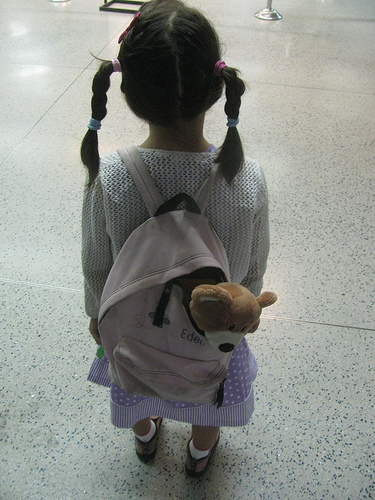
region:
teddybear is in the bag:
[181, 278, 290, 359]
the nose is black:
[219, 341, 237, 359]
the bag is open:
[109, 248, 235, 411]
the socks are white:
[183, 439, 209, 456]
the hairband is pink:
[109, 57, 120, 73]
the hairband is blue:
[88, 119, 97, 128]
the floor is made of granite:
[287, 82, 337, 183]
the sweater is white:
[107, 165, 260, 227]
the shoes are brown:
[185, 431, 220, 477]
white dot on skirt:
[231, 371, 237, 386]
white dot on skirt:
[125, 395, 130, 404]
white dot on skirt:
[129, 392, 138, 406]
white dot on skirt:
[107, 387, 118, 400]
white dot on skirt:
[111, 379, 117, 390]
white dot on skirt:
[119, 392, 131, 407]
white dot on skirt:
[166, 399, 176, 408]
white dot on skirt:
[183, 401, 191, 406]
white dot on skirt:
[233, 345, 243, 356]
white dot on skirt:
[239, 361, 248, 379]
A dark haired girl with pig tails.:
[82, 2, 269, 475]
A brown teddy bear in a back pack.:
[186, 280, 279, 354]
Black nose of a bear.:
[219, 342, 235, 352]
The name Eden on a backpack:
[179, 327, 205, 346]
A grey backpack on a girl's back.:
[96, 147, 231, 408]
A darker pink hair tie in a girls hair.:
[214, 57, 227, 77]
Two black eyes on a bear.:
[227, 322, 246, 331]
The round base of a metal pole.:
[256, 7, 282, 21]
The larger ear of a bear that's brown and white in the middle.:
[191, 284, 231, 302]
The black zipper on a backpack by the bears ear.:
[163, 279, 174, 297]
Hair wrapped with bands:
[69, 0, 252, 187]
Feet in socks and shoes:
[123, 413, 235, 475]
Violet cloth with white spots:
[81, 334, 261, 430]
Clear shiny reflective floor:
[0, 0, 374, 499]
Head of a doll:
[185, 279, 279, 352]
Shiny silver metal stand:
[253, 0, 285, 24]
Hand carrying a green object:
[84, 312, 109, 362]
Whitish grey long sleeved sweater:
[76, 139, 274, 324]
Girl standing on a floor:
[0, 0, 373, 498]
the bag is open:
[124, 206, 242, 405]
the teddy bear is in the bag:
[194, 281, 264, 358]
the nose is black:
[218, 340, 238, 352]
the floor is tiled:
[303, 357, 333, 476]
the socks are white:
[189, 440, 209, 461]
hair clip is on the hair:
[108, 12, 150, 42]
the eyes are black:
[230, 322, 246, 332]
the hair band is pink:
[110, 53, 128, 74]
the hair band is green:
[90, 120, 102, 129]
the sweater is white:
[103, 159, 264, 234]